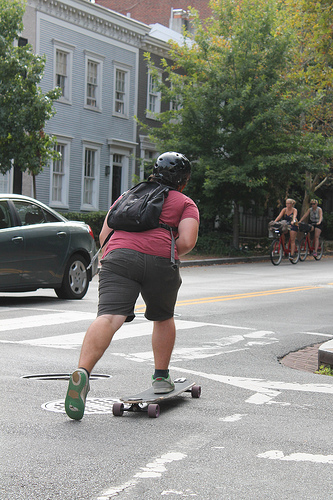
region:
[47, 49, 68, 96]
Large window on a building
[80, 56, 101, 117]
Large window on a building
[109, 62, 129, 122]
Large window on a building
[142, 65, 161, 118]
Large window on a building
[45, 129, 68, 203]
Large window on a building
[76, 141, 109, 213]
Large window on a building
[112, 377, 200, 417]
skateboard on top of the street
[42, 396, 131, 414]
metal manhole cover next to skateboard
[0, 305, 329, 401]
crosswalk painted on top of the street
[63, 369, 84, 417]
sole of shoe is green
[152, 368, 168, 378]
black sock visible above shoe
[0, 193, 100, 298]
car is stopped in the middle of the crosswalk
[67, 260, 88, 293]
silver hubcap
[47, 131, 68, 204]
window is below the window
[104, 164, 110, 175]
carriage light mounted next to door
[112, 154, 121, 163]
transom window above door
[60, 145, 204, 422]
A guy riding a skateboard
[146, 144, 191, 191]
A helmet is black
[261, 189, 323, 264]
Two people riding bicycles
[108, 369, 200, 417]
A foot on a skateboard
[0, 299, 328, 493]
White lines on the street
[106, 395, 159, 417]
Two wheels of a skateboard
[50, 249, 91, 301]
A round black tire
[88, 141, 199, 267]
Guy carrying a backpack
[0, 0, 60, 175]
Green leaves on a tree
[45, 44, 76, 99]
Large window on a building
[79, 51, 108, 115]
Large window on a building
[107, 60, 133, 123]
Large window on a building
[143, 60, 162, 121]
Large window on a building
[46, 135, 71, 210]
Large window on a building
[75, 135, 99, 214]
Large window on a building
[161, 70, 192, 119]
Large window on a building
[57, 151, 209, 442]
PErson on a skateboard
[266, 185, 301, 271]
Woman on a bicycke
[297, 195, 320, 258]
Woman on a bicycke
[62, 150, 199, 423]
a boy riding a skateboard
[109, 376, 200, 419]
a boy's wood skateboard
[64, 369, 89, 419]
a boy's left foot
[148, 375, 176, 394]
a boy's right foot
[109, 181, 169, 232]
a black canvas backpack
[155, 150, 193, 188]
a boy's black helmet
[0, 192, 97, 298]
a subcompact car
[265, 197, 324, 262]
two ladies riding a tandem bike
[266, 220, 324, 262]
a red tandem bike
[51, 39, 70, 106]
window in a house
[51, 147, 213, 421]
man wearing a helmet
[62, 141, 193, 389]
man wearing red shirt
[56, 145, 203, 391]
man wearing gray shorts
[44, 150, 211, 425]
man wearing green shoes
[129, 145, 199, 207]
a person wearing a black helmet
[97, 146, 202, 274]
a person wearing a red T-shirt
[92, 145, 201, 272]
The back of the person wearing a backpack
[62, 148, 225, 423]
A person riding a skateboard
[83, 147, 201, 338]
a Person wearing black shorts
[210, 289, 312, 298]
A yellow center divider line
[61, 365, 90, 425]
the green bottom of a tennis shoe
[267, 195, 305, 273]
A woman riding a bicycle in the street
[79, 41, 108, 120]
Windows on a grey building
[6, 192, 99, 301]
A gray four-door car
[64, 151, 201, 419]
a person riding a skateboard